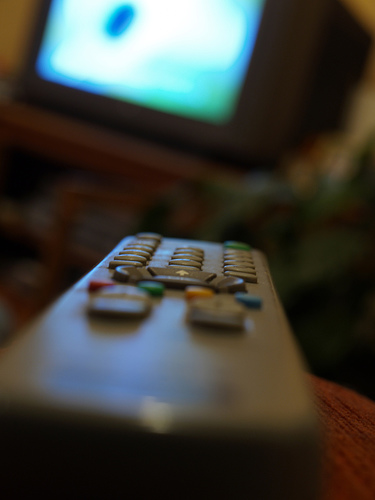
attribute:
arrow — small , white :
[174, 268, 190, 276]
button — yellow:
[185, 286, 213, 301]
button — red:
[234, 292, 263, 310]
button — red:
[86, 273, 109, 292]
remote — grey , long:
[23, 214, 327, 432]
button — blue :
[229, 283, 270, 311]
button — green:
[139, 279, 163, 297]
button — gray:
[222, 264, 252, 283]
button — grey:
[193, 305, 246, 336]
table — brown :
[324, 388, 354, 441]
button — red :
[84, 274, 118, 294]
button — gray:
[133, 272, 212, 306]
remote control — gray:
[12, 229, 324, 463]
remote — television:
[93, 202, 301, 394]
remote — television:
[9, 233, 318, 498]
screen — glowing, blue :
[34, 0, 264, 126]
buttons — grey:
[219, 244, 258, 285]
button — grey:
[136, 230, 162, 243]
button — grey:
[129, 237, 159, 249]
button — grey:
[169, 256, 203, 268]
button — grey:
[106, 258, 144, 271]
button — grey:
[222, 268, 260, 283]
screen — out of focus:
[16, 0, 366, 164]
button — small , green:
[225, 235, 250, 252]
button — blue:
[233, 289, 262, 309]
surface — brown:
[6, 282, 362, 496]